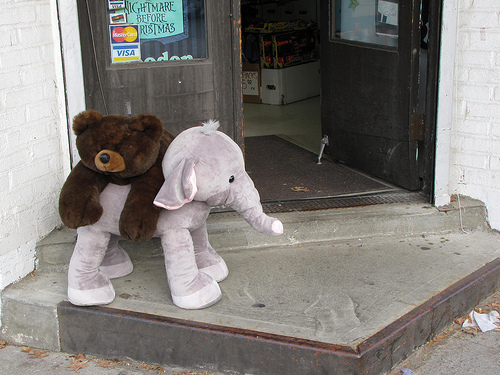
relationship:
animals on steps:
[57, 107, 284, 309] [0, 193, 499, 374]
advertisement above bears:
[121, 1, 185, 44] [57, 107, 284, 309]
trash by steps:
[460, 306, 498, 333] [0, 193, 499, 374]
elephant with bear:
[66, 119, 284, 311] [59, 109, 175, 241]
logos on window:
[109, 24, 139, 65] [103, 1, 208, 66]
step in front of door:
[0, 193, 499, 374] [314, 1, 424, 191]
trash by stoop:
[460, 306, 498, 333] [0, 193, 499, 374]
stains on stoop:
[400, 233, 473, 257] [0, 193, 499, 374]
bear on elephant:
[59, 109, 175, 241] [66, 119, 284, 311]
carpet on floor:
[244, 135, 401, 203] [236, 91, 410, 201]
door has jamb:
[314, 1, 424, 191] [254, 190, 431, 216]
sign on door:
[109, 23, 140, 46] [73, 0, 245, 172]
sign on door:
[109, 11, 129, 27] [73, 0, 245, 172]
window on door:
[103, 1, 208, 66] [73, 0, 245, 172]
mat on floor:
[244, 135, 401, 203] [236, 91, 410, 201]